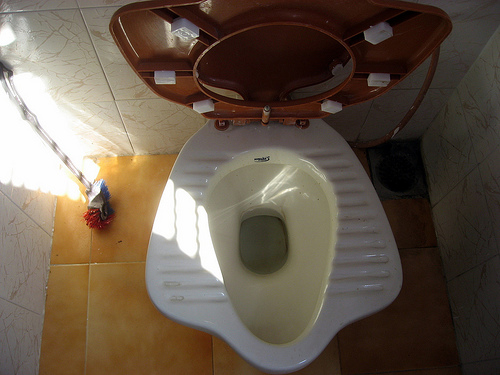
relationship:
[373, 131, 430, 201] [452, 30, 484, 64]
cleaner on wall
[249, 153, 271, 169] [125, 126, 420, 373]
logo on seat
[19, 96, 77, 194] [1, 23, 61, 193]
sunlight coming window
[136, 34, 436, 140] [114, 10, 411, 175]
cushions on seat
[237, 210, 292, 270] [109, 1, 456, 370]
tunnel in toilet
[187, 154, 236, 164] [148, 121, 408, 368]
ridge on a seat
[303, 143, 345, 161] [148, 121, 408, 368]
ridge on a seat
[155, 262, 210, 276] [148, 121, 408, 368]
ridge on a seat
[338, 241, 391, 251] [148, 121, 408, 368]
ridge on a seat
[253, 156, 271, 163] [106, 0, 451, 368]
logo in a toilet bowl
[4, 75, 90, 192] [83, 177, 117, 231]
handle on brush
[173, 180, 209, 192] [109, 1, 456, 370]
line on toilet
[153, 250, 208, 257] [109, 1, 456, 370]
line on toilet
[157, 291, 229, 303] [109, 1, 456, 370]
line on toilet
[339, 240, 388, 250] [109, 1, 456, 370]
line on toilet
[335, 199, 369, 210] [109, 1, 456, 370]
line on toilet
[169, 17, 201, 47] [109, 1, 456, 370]
sponge on toilet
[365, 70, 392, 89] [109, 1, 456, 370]
sponge on toilet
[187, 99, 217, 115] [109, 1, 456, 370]
sponge on toilet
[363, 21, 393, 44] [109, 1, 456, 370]
sponge on toilet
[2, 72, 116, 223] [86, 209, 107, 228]
scrubber with bristles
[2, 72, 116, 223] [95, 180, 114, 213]
scrubber with bristles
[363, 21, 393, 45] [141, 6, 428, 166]
sponge on lid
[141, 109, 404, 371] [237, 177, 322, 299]
seat on bowl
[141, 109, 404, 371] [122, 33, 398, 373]
seat on toilet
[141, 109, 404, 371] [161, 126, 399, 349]
seat on toilet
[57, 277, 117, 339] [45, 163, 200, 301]
tile in bathroom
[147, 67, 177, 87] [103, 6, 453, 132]
square on bottom of a seat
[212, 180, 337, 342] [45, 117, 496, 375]
water in bathroom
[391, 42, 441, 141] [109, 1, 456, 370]
cord running down toilet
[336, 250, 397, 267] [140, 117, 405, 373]
ridge in porcelain toilet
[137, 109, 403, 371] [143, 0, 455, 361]
seat on toilet